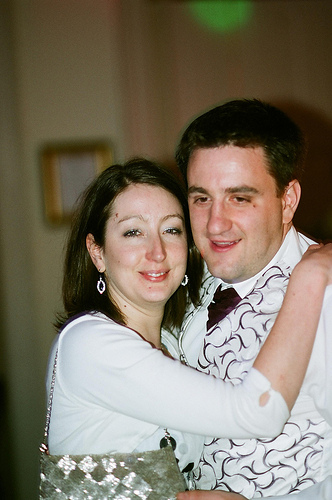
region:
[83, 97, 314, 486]
a man and woman hugging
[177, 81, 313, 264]
a man with short hair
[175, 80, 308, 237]
a man with brown hair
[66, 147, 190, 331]
a woman with brown hair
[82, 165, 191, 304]
a woman wearing ear rings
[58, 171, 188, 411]
a woman wearing a white shirt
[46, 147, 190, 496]
a woman with a purse on her sholder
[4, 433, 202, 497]
a silver sequined purse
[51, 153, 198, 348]
a woman with shoulder length hair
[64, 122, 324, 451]
a woman with her hand on a man's shoulder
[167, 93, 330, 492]
a man standing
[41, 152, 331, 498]
a woman hugging a man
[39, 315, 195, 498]
a silver sequined purse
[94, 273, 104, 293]
a diamond hoop earring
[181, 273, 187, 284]
a diamond hoop earring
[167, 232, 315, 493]
a white and maroon vest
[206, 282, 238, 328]
a maroon neck tie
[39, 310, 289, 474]
a white woman's blouse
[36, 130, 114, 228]
a gold framed mirror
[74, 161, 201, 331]
a smiling woman's face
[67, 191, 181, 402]
this is a lady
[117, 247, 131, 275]
the lady is light skinned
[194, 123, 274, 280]
this is a man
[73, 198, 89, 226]
this is the hair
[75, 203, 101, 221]
the hair is black in color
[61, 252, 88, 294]
the hair is long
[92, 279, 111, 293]
this is a earing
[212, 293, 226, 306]
this is a neck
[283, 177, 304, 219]
this is the ear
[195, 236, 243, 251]
the man is laughing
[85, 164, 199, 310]
head of the lady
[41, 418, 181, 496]
purse next to the lady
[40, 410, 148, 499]
silver purse on lady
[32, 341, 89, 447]
strap of the purse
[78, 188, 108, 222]
hair on lady's head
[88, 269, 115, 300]
earring on girl's ear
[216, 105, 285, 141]
brown hair on guy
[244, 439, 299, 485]
pattern on the shirt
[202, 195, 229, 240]
nose of the man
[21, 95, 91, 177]
blurry background of the photo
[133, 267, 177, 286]
THE WOMAN IS SMILING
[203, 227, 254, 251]
THE MAN IS SMILING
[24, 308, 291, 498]
THE WOMAN IS WEARING A WHITE SHIRT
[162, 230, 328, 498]
THE MAN IS WEARING A WHITE SHIRT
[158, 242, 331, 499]
THE MAN IS WEARING A BLACK AND WHITE VEST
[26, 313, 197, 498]
THE WOMAN IS WEARING A SILVER PURSE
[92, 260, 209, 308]
THE WOMAN IS WEARING EARRINGS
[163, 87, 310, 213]
THE MAN HAS SHORT HAIR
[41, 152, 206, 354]
THE WOMAN HAS BROWN HAIR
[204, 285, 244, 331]
THE MAN IS WEARING A TIE